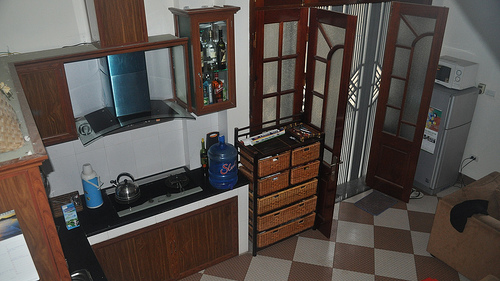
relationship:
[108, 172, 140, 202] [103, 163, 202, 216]
kettle on cooktop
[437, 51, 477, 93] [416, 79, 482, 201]
microwave on refrigerator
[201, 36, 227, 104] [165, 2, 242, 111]
bottles in cabinet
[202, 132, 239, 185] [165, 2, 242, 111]
bottles in cabinet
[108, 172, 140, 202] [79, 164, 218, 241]
kettle on back stove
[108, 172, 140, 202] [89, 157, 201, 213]
kettle on top of black stove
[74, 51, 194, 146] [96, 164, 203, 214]
hood over stove top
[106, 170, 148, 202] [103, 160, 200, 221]
kettle on range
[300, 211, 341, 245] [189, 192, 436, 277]
shape on floor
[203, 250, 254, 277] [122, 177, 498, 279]
shape on floor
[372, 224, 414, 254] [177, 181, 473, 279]
diamond shape on floor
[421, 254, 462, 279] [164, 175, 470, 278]
shape on floor